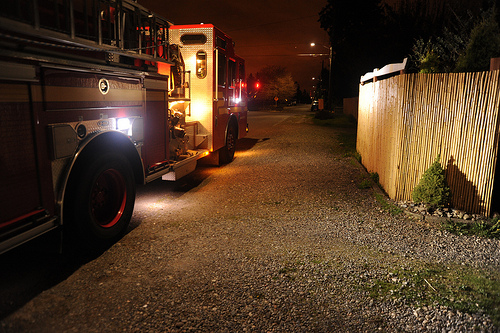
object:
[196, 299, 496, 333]
gravel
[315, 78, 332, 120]
pole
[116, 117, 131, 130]
light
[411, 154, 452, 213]
tree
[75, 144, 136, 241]
tire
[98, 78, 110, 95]
cap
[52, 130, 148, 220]
fender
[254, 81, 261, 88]
signal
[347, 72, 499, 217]
fence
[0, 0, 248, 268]
truck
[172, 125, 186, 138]
cuffs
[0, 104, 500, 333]
road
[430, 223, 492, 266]
gravel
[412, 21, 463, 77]
plant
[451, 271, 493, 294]
grass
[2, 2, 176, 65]
ladder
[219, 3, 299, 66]
sky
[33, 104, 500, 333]
sidewalk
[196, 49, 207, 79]
window